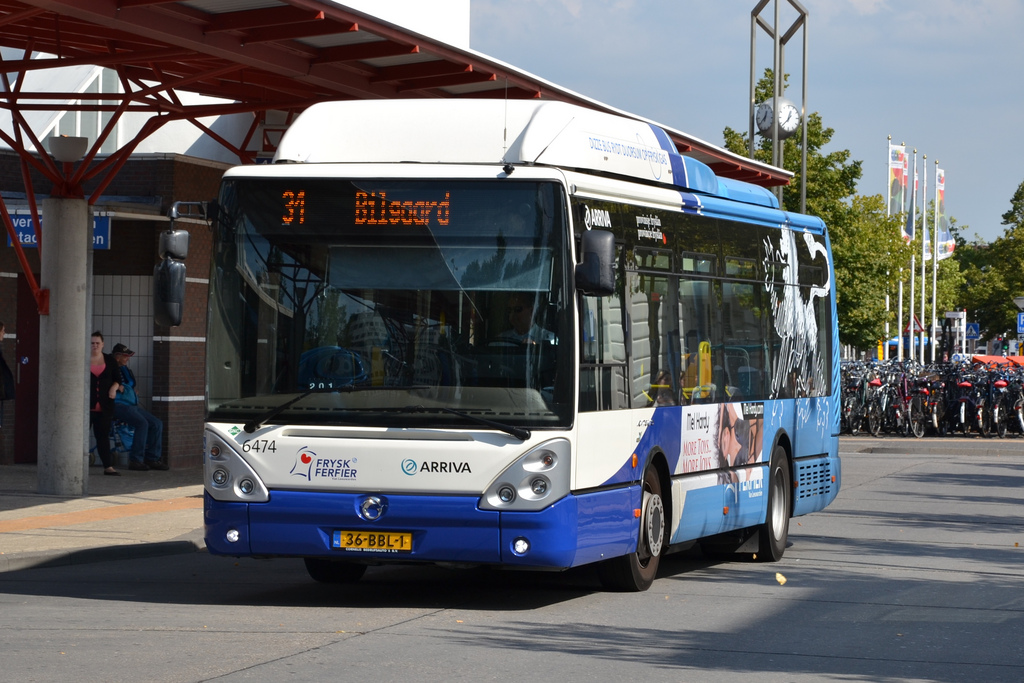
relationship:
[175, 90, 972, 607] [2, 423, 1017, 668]
bus on road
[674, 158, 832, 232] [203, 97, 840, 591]
trim on bus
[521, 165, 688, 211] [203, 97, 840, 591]
trim on bus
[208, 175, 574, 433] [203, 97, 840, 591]
window on bus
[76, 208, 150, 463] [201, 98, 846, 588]
wall on side of building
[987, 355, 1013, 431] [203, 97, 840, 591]
motorcycle behind bus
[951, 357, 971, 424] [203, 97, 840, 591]
motorcycle behind bus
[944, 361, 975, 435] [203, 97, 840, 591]
motorcycle behind bus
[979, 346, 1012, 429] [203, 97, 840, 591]
motorcycle behind bus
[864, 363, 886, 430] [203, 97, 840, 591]
motorcycle behind bus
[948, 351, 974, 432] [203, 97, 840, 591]
motorcycle behind bus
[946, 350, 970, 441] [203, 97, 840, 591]
motorcycle behind bus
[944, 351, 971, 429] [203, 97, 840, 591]
motorcycle behind bus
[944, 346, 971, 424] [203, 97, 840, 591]
motorcycle behind bus